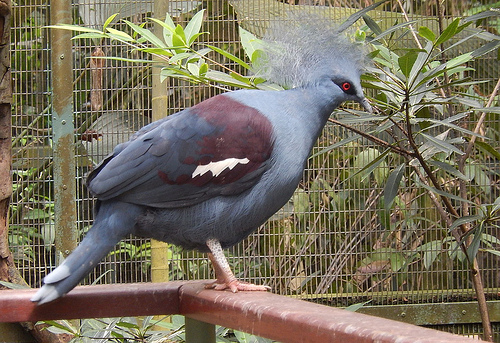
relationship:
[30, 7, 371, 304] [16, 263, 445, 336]
bird on porch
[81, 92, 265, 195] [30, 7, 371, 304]
wing on bird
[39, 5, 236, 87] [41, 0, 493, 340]
leaves on plant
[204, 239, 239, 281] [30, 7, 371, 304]
back on bird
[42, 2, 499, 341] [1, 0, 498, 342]
tree on enclosure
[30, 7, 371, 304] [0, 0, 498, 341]
bird on cage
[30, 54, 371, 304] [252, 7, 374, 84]
bird on weather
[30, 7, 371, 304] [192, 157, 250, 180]
bird on feather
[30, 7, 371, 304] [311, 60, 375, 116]
bird has head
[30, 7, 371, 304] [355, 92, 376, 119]
bird has beak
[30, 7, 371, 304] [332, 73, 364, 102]
bird has eye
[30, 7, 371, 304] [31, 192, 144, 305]
bird has tail feathers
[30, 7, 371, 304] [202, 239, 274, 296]
bird has legs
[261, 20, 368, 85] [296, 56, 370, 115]
hair on head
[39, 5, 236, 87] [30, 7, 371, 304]
leaves next bird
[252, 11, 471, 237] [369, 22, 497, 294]
branches on tree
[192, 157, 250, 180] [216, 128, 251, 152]
feather seen part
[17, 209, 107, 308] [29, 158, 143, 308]
feather on back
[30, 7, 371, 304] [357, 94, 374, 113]
bird has beak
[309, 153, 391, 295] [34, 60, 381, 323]
fence near bird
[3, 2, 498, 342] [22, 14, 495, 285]
foliage in enclosure